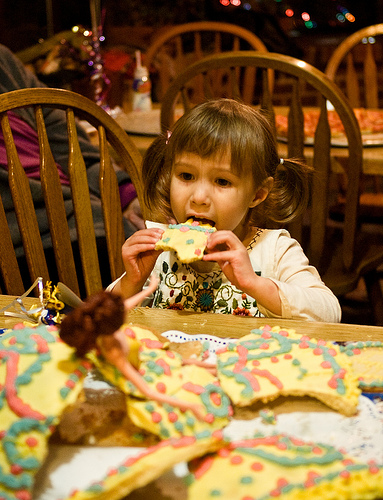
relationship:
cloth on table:
[40, 331, 381, 497] [0, 294, 382, 498]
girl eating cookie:
[105, 100, 341, 328] [154, 214, 212, 263]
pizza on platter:
[269, 108, 383, 138] [287, 132, 381, 150]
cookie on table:
[218, 323, 362, 415] [0, 295, 383, 500]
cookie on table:
[346, 337, 381, 391] [0, 295, 383, 500]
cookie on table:
[193, 429, 380, 498] [0, 295, 383, 500]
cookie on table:
[77, 430, 228, 496] [0, 295, 383, 500]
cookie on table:
[3, 322, 88, 491] [0, 295, 383, 500]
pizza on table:
[269, 108, 383, 138] [47, 79, 382, 199]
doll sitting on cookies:
[59, 271, 216, 425] [0, 320, 380, 498]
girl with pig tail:
[134, 93, 275, 228] [258, 157, 318, 227]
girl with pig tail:
[134, 93, 275, 228] [137, 126, 173, 224]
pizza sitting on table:
[269, 103, 381, 151] [96, 108, 381, 191]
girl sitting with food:
[105, 100, 341, 328] [153, 217, 218, 264]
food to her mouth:
[153, 217, 218, 264] [183, 211, 217, 228]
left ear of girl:
[249, 175, 277, 211] [105, 100, 341, 328]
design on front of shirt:
[159, 263, 262, 316] [106, 228, 341, 323]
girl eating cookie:
[105, 100, 341, 328] [144, 203, 232, 267]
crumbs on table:
[172, 309, 215, 333] [0, 294, 381, 340]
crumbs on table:
[1, 272, 366, 493] [0, 294, 381, 340]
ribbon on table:
[2, 263, 59, 335] [0, 293, 196, 338]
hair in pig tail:
[136, 100, 302, 224] [254, 151, 318, 229]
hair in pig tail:
[136, 100, 302, 224] [138, 128, 183, 220]